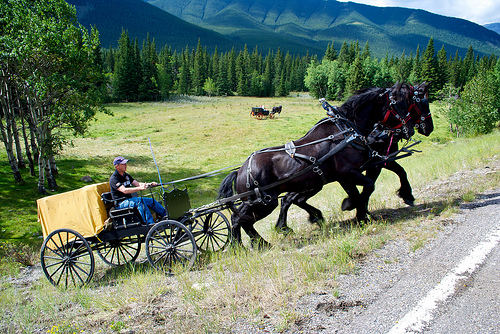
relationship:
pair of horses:
[221, 73, 435, 260] [222, 77, 433, 248]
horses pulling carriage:
[222, 77, 433, 248] [31, 159, 226, 290]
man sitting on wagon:
[107, 157, 166, 224] [34, 167, 277, 292]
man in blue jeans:
[107, 157, 166, 224] [117, 197, 152, 222]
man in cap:
[107, 157, 166, 224] [112, 154, 131, 168]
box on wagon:
[32, 179, 112, 249] [34, 167, 277, 292]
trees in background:
[107, 27, 476, 90] [71, 10, 470, 81]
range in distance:
[118, 6, 447, 60] [111, 6, 461, 70]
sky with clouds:
[403, 6, 482, 29] [472, 6, 482, 17]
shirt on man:
[109, 176, 135, 200] [105, 158, 157, 222]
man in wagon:
[105, 158, 157, 222] [34, 167, 277, 292]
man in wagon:
[107, 157, 166, 224] [34, 167, 277, 292]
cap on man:
[112, 154, 132, 165] [107, 157, 166, 224]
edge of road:
[372, 231, 476, 324] [389, 222, 485, 322]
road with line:
[389, 222, 485, 322] [410, 238, 481, 326]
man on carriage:
[107, 157, 166, 224] [19, 158, 251, 282]